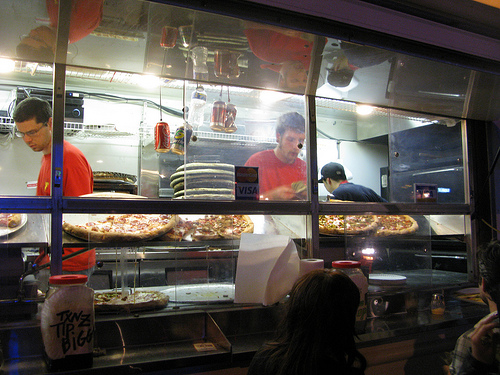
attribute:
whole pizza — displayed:
[63, 191, 180, 245]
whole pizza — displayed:
[161, 215, 254, 242]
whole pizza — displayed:
[318, 213, 383, 236]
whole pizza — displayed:
[375, 215, 419, 235]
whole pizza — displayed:
[94, 290, 170, 312]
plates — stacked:
[368, 273, 407, 287]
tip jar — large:
[40, 275, 95, 371]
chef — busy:
[318, 163, 388, 203]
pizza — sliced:
[160, 221, 194, 243]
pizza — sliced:
[0, 212, 23, 228]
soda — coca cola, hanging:
[154, 121, 170, 151]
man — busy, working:
[12, 98, 95, 294]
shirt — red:
[35, 141, 97, 271]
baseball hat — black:
[318, 162, 348, 182]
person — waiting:
[246, 267, 368, 374]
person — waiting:
[442, 239, 499, 374]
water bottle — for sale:
[187, 86, 206, 128]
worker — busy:
[245, 112, 309, 237]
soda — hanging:
[170, 127, 192, 155]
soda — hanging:
[210, 100, 226, 132]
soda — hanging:
[224, 103, 238, 133]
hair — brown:
[13, 97, 52, 126]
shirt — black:
[332, 182, 390, 203]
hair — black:
[321, 175, 347, 183]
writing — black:
[50, 310, 93, 352]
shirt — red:
[234, 150, 307, 200]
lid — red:
[49, 274, 89, 285]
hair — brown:
[256, 268, 367, 374]